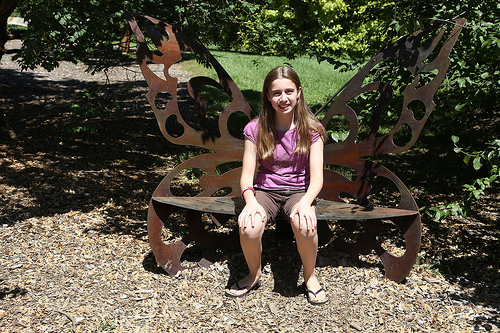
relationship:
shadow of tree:
[14, 70, 457, 255] [21, 5, 480, 105]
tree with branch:
[41, 14, 481, 120] [31, 2, 91, 33]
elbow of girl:
[237, 168, 247, 178] [235, 66, 324, 299]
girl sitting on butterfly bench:
[232, 68, 330, 301] [122, 7, 468, 282]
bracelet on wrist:
[240, 186, 257, 200] [239, 181, 252, 202]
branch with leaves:
[432, 169, 483, 230] [430, 176, 484, 219]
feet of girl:
[223, 270, 333, 306] [235, 66, 324, 299]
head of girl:
[264, 63, 307, 121] [222, 63, 331, 307]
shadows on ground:
[2, 66, 490, 331] [2, 19, 498, 330]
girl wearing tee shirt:
[222, 63, 331, 307] [243, 122, 324, 194]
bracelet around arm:
[236, 187, 257, 197] [240, 120, 266, 230]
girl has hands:
[222, 63, 331, 307] [233, 200, 320, 233]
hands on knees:
[233, 200, 320, 233] [237, 216, 321, 248]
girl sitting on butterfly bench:
[222, 63, 331, 307] [122, 7, 468, 282]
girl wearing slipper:
[222, 63, 331, 307] [221, 277, 259, 299]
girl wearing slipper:
[222, 63, 331, 307] [301, 281, 329, 304]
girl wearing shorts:
[222, 63, 331, 307] [250, 188, 315, 222]